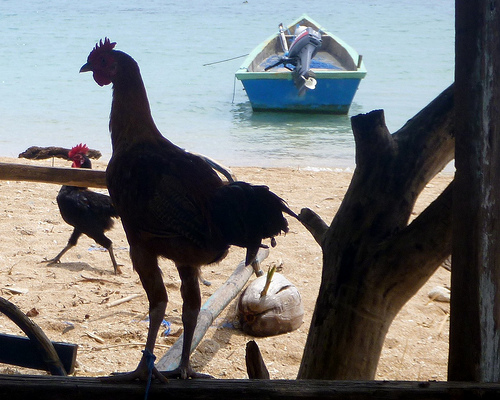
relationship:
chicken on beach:
[50, 186, 127, 271] [1, 178, 78, 324]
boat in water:
[232, 14, 367, 116] [2, 2, 457, 174]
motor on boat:
[285, 28, 322, 90] [232, 14, 367, 116]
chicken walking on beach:
[79, 32, 298, 396] [28, 106, 497, 244]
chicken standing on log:
[79, 32, 298, 396] [149, 246, 275, 371]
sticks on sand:
[66, 265, 139, 345] [29, 269, 126, 315]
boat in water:
[223, 6, 380, 126] [46, 0, 500, 170]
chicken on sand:
[79, 32, 298, 396] [5, 154, 455, 383]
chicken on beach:
[68, 37, 313, 381] [1, 156, 498, 322]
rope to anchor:
[204, 52, 249, 67] [217, 73, 237, 141]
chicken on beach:
[40, 144, 124, 278] [1, 143, 493, 399]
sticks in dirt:
[77, 272, 143, 330] [4, 158, 454, 384]